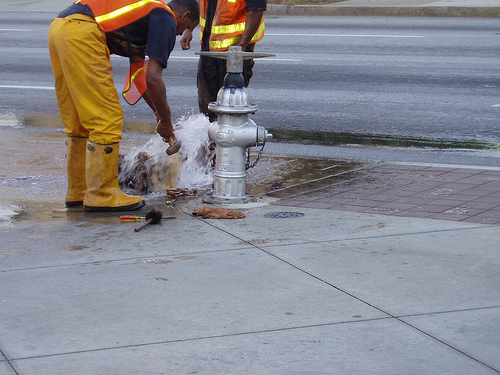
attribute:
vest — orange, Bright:
[200, 0, 265, 47]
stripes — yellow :
[197, 12, 262, 47]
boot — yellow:
[80, 132, 153, 217]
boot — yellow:
[51, 125, 92, 209]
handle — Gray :
[196, 44, 276, 72]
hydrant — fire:
[38, 0, 263, 215]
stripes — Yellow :
[191, 11, 271, 54]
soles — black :
[63, 199, 145, 214]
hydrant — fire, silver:
[190, 47, 278, 206]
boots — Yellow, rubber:
[57, 135, 149, 214]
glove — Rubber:
[185, 200, 242, 232]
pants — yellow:
[29, 10, 116, 159]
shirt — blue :
[39, 1, 186, 66]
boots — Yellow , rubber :
[74, 120, 185, 224]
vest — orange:
[77, 0, 178, 102]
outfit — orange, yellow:
[75, 3, 181, 31]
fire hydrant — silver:
[187, 46, 276, 218]